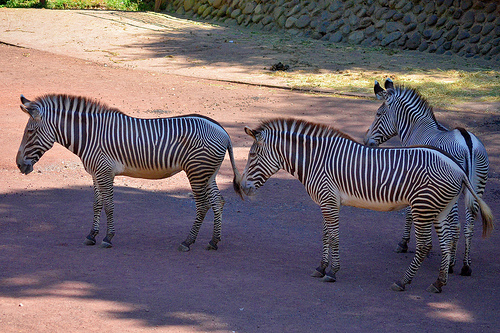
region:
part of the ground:
[234, 240, 281, 292]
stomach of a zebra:
[348, 160, 400, 207]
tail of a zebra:
[453, 161, 495, 240]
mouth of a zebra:
[231, 173, 262, 198]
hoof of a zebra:
[321, 274, 332, 287]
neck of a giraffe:
[284, 147, 308, 180]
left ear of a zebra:
[14, 93, 33, 119]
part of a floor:
[311, 40, 350, 80]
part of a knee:
[413, 232, 429, 261]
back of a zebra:
[358, 142, 433, 166]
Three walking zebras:
[25, 74, 493, 291]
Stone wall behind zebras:
[136, 5, 494, 55]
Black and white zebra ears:
[14, 88, 52, 125]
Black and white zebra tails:
[440, 124, 496, 231]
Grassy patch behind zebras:
[261, 34, 488, 105]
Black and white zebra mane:
[393, 81, 442, 124]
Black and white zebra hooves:
[74, 205, 235, 262]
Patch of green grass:
[7, 0, 148, 12]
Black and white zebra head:
[5, 92, 62, 177]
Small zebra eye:
[243, 150, 259, 161]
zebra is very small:
[5, 66, 260, 294]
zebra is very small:
[231, 90, 481, 325]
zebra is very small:
[342, 100, 462, 229]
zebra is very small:
[3, 63, 203, 214]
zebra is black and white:
[213, 90, 494, 283]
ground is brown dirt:
[39, 188, 341, 328]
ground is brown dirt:
[128, 144, 424, 329]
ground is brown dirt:
[129, 249, 461, 311]